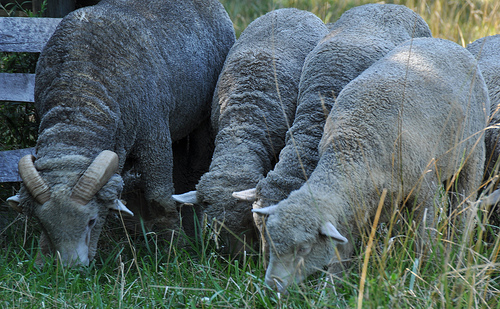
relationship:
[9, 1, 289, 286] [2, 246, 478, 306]
goat eating grass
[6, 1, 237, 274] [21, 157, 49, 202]
goat has horns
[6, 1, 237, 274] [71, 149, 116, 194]
goat has horns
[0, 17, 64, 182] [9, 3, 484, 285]
fence behind goats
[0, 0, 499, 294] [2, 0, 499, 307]
sheep grazaing on grass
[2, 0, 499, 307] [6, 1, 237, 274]
grass being eaten by goat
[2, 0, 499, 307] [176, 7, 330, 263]
grass being eaten by sheep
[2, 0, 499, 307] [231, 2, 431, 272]
grass being eaten by sheep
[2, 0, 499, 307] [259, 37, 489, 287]
grass being eaten by sheep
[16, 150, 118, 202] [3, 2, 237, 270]
antlers on ram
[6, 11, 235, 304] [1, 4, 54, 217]
ram eating by fence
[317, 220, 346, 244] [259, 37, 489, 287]
ear of sheep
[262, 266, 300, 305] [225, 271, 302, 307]
nose hidden by some grass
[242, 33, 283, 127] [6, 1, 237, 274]
wool on goat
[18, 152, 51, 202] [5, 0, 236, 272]
horn on ram head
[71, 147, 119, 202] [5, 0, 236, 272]
horn on ram head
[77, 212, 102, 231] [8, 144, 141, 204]
eye on ram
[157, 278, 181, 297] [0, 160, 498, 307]
part of a grass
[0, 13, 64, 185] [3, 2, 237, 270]
fence next to ram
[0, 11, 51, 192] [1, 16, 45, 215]
three boards of a fence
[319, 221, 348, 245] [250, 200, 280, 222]
ear of a ear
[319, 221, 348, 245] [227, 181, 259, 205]
ear of a ear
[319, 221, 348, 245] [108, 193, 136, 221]
ear of a ear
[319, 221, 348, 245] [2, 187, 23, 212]
ear of a ear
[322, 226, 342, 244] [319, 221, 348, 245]
edge of a ear